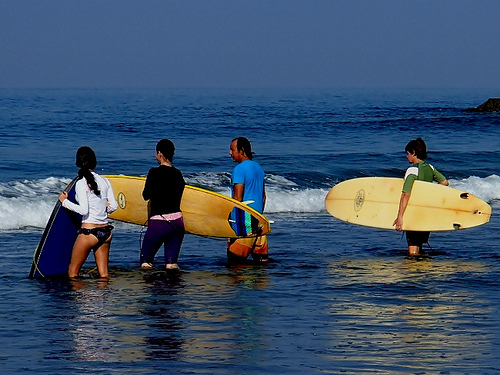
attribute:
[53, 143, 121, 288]
woman — standing, tanned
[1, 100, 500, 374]
water — blue, wavy, wet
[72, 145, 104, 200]
hair — dark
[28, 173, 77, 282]
surfboard — blue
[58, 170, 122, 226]
shirt — white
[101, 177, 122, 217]
sleeve — long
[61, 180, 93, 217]
sleeve — long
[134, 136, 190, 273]
woman — standing, water, wet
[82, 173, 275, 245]
surfboard — yellow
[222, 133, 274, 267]
man — standing, wet